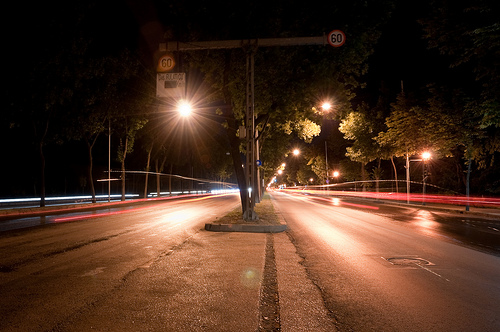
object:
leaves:
[490, 112, 492, 116]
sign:
[157, 70, 188, 99]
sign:
[329, 30, 347, 46]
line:
[413, 255, 452, 284]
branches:
[388, 157, 399, 192]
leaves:
[370, 131, 376, 135]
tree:
[337, 109, 387, 197]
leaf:
[309, 121, 313, 126]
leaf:
[289, 119, 297, 126]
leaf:
[298, 108, 308, 116]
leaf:
[296, 113, 303, 117]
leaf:
[300, 131, 309, 135]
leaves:
[404, 120, 409, 125]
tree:
[67, 5, 149, 205]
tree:
[415, 0, 500, 212]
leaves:
[7, 105, 16, 112]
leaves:
[354, 58, 362, 64]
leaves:
[483, 103, 485, 107]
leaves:
[486, 101, 494, 109]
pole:
[321, 92, 330, 194]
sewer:
[382, 252, 435, 269]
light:
[332, 197, 345, 206]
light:
[172, 96, 200, 117]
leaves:
[232, 88, 240, 93]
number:
[335, 33, 343, 44]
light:
[315, 98, 337, 113]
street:
[0, 191, 500, 331]